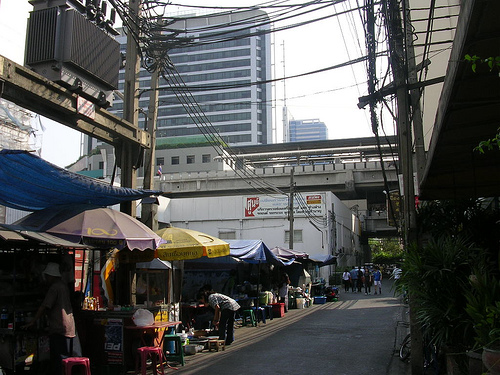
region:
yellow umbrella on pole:
[143, 224, 233, 286]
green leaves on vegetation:
[415, 232, 477, 307]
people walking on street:
[338, 262, 385, 296]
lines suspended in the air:
[196, 105, 299, 214]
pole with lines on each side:
[273, 163, 303, 240]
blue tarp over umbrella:
[28, 165, 110, 222]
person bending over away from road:
[194, 284, 241, 347]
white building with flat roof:
[208, 182, 343, 241]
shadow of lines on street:
[307, 294, 357, 318]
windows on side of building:
[207, 43, 245, 119]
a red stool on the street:
[116, 340, 172, 374]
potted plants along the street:
[394, 188, 495, 370]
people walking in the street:
[346, 242, 392, 314]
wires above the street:
[135, 10, 412, 138]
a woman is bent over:
[188, 270, 241, 342]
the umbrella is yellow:
[143, 215, 230, 273]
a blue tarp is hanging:
[0, 134, 160, 209]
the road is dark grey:
[247, 311, 391, 360]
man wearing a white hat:
[21, 250, 83, 361]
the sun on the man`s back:
[49, 300, 96, 340]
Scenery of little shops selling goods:
[14, 8, 411, 373]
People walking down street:
[334, 257, 399, 304]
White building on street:
[159, 185, 366, 301]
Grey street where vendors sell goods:
[286, 316, 388, 365]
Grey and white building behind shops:
[86, 11, 283, 160]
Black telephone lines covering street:
[31, 5, 435, 96]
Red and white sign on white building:
[231, 190, 336, 227]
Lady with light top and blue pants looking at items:
[191, 280, 246, 350]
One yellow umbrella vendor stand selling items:
[148, 211, 234, 293]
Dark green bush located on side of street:
[409, 205, 499, 330]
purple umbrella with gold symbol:
[41, 202, 158, 254]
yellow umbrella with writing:
[153, 215, 230, 273]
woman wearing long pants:
[198, 286, 244, 343]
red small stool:
[132, 339, 171, 373]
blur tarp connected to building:
[5, 150, 154, 206]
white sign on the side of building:
[242, 190, 334, 225]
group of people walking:
[340, 262, 385, 297]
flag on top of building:
[154, 160, 167, 182]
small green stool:
[238, 307, 257, 326]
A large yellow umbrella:
[144, 211, 236, 271]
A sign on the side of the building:
[236, 189, 339, 229]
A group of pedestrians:
[324, 241, 409, 299]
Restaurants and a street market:
[9, 272, 342, 372]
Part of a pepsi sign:
[98, 311, 138, 366]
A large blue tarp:
[0, 137, 173, 215]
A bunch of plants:
[399, 227, 499, 370]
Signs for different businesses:
[378, 186, 435, 230]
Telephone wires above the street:
[166, 99, 301, 211]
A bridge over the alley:
[169, 134, 399, 196]